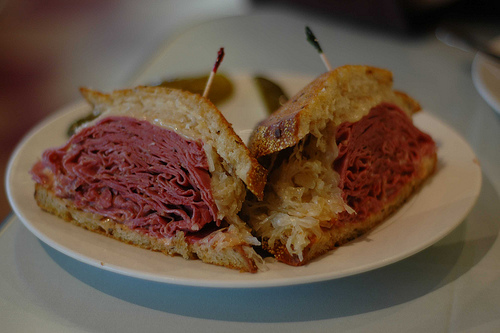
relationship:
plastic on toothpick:
[210, 44, 227, 74] [204, 47, 225, 98]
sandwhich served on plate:
[27, 83, 272, 276] [5, 68, 484, 290]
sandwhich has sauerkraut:
[245, 60, 440, 268] [260, 156, 355, 235]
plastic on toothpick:
[209, 32, 228, 83] [195, 39, 227, 92]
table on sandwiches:
[0, 1, 499, 332] [20, 50, 477, 279]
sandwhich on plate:
[27, 83, 272, 276] [5, 68, 484, 290]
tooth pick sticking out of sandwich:
[200, 46, 227, 98] [31, 85, 265, 276]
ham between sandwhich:
[23, 114, 235, 247] [27, 83, 272, 276]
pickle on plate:
[245, 67, 292, 113] [5, 68, 484, 290]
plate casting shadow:
[5, 68, 484, 290] [39, 170, 498, 320]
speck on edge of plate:
[95, 259, 107, 267] [5, 68, 484, 290]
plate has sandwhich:
[5, 68, 484, 290] [27, 83, 272, 276]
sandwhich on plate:
[27, 83, 272, 276] [0, 84, 498, 292]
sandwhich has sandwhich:
[52, 76, 285, 272] [27, 83, 272, 276]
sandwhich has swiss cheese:
[27, 83, 272, 276] [73, 91, 208, 142]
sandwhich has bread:
[27, 83, 272, 276] [23, 174, 253, 272]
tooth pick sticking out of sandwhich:
[196, 35, 231, 86] [36, 85, 265, 280]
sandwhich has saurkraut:
[209, 22, 454, 275] [261, 131, 351, 269]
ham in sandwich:
[33, 104, 221, 234] [17, 60, 276, 269]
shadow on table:
[53, 212, 490, 308] [6, 10, 487, 330]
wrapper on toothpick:
[297, 16, 327, 57] [300, 8, 334, 70]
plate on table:
[4, 68, 484, 289] [8, 102, 498, 333]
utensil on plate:
[442, 52, 497, 72] [480, 99, 489, 104]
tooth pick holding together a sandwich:
[200, 46, 227, 98] [75, 119, 456, 259]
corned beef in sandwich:
[82, 151, 154, 204] [62, 132, 200, 229]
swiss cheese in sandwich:
[110, 113, 220, 151] [54, 86, 244, 233]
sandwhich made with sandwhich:
[245, 60, 440, 268] [245, 60, 440, 268]